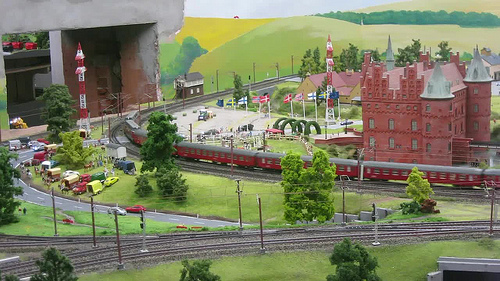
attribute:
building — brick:
[359, 82, 455, 175]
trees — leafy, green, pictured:
[135, 124, 187, 184]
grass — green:
[189, 183, 222, 211]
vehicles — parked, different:
[39, 155, 104, 205]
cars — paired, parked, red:
[87, 196, 184, 234]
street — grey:
[157, 213, 230, 233]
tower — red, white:
[60, 45, 105, 120]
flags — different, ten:
[229, 79, 355, 116]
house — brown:
[163, 65, 224, 106]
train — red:
[185, 141, 281, 171]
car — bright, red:
[81, 174, 132, 197]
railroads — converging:
[174, 135, 483, 264]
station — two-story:
[361, 81, 456, 169]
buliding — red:
[338, 80, 476, 160]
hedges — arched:
[277, 116, 336, 147]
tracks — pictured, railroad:
[41, 233, 160, 259]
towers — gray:
[373, 37, 490, 101]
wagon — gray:
[115, 157, 136, 174]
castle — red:
[314, 58, 458, 141]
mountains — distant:
[200, 5, 483, 24]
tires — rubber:
[69, 190, 110, 213]